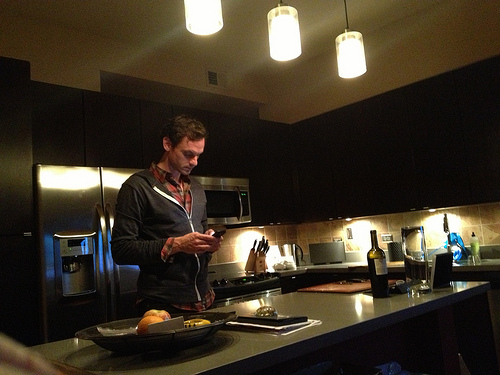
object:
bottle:
[365, 227, 392, 299]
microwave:
[186, 174, 256, 225]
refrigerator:
[36, 162, 107, 342]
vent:
[204, 66, 232, 90]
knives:
[251, 236, 260, 252]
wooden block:
[240, 237, 270, 277]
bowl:
[71, 307, 241, 356]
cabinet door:
[31, 80, 85, 167]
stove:
[205, 261, 307, 304]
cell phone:
[212, 229, 228, 238]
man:
[110, 116, 224, 317]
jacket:
[107, 168, 211, 303]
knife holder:
[242, 235, 273, 277]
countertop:
[239, 244, 500, 281]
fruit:
[138, 309, 213, 331]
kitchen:
[1, 0, 497, 375]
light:
[334, 26, 370, 81]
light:
[267, 1, 303, 63]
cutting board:
[298, 276, 398, 295]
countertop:
[24, 275, 494, 375]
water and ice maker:
[46, 229, 105, 299]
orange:
[136, 311, 168, 335]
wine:
[364, 229, 394, 300]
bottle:
[468, 228, 484, 263]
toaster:
[307, 238, 349, 264]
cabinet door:
[0, 54, 37, 236]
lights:
[183, 1, 230, 37]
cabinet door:
[290, 107, 336, 221]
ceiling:
[1, 0, 500, 120]